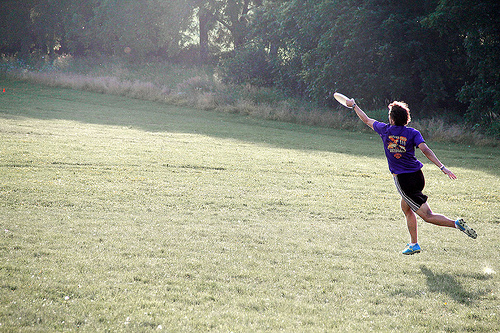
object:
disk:
[333, 92, 353, 108]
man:
[346, 98, 478, 256]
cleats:
[454, 218, 477, 239]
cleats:
[402, 243, 423, 256]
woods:
[0, 0, 499, 124]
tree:
[256, 6, 289, 78]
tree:
[304, 12, 368, 95]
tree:
[410, 13, 484, 106]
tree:
[119, 11, 164, 63]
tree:
[44, 9, 82, 67]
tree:
[10, 6, 50, 55]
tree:
[184, 0, 252, 74]